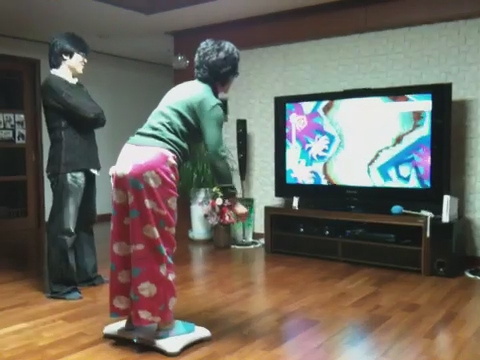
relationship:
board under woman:
[102, 319, 211, 357] [111, 37, 250, 336]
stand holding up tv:
[265, 204, 432, 275] [274, 81, 453, 213]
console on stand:
[442, 192, 459, 224] [265, 204, 432, 275]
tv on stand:
[274, 81, 453, 213] [265, 204, 432, 275]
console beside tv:
[442, 192, 459, 224] [274, 81, 453, 213]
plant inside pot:
[181, 144, 214, 191] [187, 189, 215, 239]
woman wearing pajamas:
[111, 37, 250, 336] [108, 144, 181, 326]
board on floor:
[102, 319, 211, 357] [176, 242, 478, 360]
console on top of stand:
[442, 192, 459, 224] [265, 204, 432, 275]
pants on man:
[48, 171, 101, 299] [40, 30, 104, 299]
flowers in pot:
[203, 200, 236, 228] [210, 222, 231, 247]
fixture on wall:
[170, 54, 189, 69] [236, 4, 479, 95]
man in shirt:
[40, 30, 104, 299] [40, 75, 107, 170]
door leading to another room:
[2, 57, 39, 235] [1, 2, 463, 350]